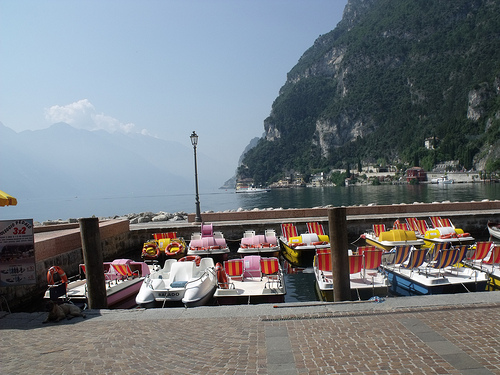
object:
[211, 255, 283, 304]
boat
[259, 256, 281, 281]
chairs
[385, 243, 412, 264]
seat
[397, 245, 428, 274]
seat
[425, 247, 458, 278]
seat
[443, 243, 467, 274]
seat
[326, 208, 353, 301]
wooden post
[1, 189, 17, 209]
umbrella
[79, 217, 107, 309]
pole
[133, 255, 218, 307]
boat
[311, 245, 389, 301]
boat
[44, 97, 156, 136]
cloud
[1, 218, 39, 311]
sign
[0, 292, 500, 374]
brick/pavement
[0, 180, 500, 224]
ocean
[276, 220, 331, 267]
boats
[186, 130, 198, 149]
lamp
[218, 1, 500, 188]
mountain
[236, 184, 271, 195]
boat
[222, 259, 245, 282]
chair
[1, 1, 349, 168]
sky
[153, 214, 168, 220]
rocks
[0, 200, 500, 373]
dock